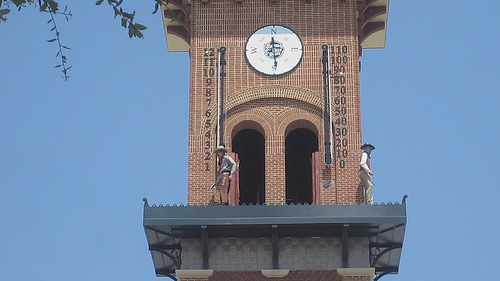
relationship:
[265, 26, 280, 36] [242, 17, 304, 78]
n on clock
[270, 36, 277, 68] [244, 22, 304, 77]
hand of compass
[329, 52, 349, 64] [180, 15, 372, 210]
number 100 on tower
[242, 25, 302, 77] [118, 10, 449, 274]
clock on building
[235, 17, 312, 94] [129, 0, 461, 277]
clock on building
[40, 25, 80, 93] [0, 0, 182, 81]
piece of tree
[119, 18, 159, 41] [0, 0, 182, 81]
piece of tree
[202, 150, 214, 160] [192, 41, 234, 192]
number to left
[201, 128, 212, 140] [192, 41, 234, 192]
number to left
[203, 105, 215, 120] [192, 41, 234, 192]
number to left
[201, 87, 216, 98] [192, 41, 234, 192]
number to left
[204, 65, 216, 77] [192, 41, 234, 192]
number to left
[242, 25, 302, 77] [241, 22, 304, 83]
clock looks compass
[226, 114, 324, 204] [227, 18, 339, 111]
archways under clock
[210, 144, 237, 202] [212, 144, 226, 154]
cowboy has hat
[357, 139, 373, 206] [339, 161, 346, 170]
cowboy beside 0